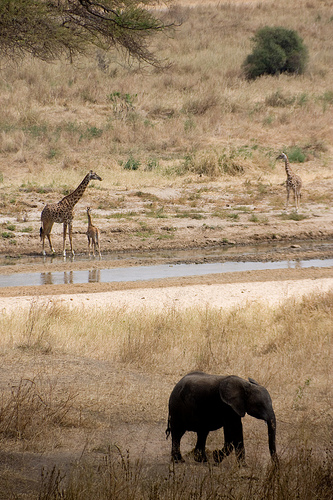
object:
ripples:
[0, 257, 333, 288]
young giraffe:
[86, 207, 101, 258]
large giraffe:
[39, 169, 103, 257]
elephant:
[165, 370, 281, 470]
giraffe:
[275, 152, 303, 213]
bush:
[237, 22, 311, 84]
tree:
[0, 0, 187, 74]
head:
[275, 151, 289, 162]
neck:
[285, 158, 297, 176]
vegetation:
[0, 20, 333, 180]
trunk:
[264, 406, 280, 474]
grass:
[118, 285, 333, 359]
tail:
[165, 397, 172, 442]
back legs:
[171, 429, 188, 464]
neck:
[72, 171, 89, 209]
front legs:
[293, 189, 300, 215]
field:
[0, 0, 330, 260]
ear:
[219, 375, 247, 418]